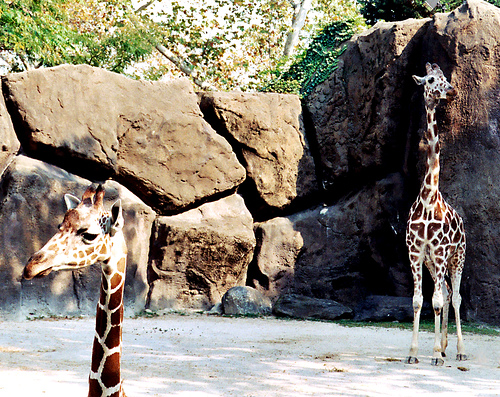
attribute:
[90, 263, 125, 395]
neck — tall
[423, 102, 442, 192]
neck — long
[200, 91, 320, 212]
big/brown stone — brown, big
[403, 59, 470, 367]
giraffe — brown, white, tall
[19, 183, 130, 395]
giraffe — brown, white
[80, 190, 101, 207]
horns — small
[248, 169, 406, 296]
stone — big, brown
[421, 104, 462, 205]
neck — tall, brown, white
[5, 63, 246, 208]
stone — big, brown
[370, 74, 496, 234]
giraffe — tall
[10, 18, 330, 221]
stone — big, brown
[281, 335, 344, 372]
ground — sandy